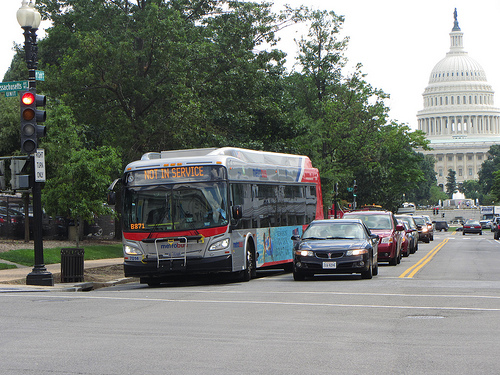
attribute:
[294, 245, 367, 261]
headlight — on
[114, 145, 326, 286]
bus — red, silver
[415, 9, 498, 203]
building — white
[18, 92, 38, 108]
light — red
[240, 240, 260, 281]
wheel — black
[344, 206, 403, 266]
vehicle — red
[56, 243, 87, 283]
garbage can — black